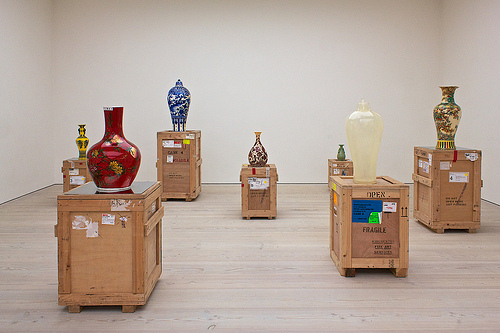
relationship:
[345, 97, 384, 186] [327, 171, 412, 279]
vase on crate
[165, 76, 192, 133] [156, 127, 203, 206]
vase on crate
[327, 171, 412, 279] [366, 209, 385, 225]
crate has label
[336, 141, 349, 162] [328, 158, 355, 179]
vase on crate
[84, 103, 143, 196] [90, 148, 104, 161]
vase has flower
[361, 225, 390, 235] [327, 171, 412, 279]
fragile on crate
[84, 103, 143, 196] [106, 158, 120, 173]
vase has flower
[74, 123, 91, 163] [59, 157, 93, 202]
vase on crate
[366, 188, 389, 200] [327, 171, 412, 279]
writing on crate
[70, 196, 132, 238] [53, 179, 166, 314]
labels on crate